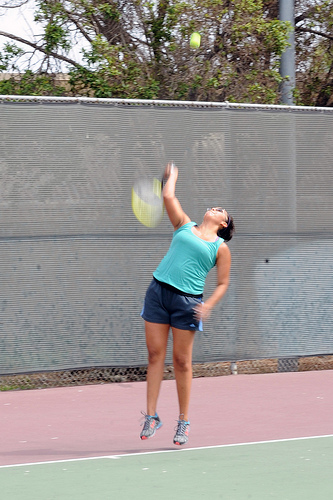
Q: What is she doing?
A: Jumping.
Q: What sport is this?
A: Lawn tennis.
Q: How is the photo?
A: Blurry.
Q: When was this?
A: Daytime.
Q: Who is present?
A: A woman.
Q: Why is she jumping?
A: To hit the ball.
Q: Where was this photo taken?
A: On a tennis court.